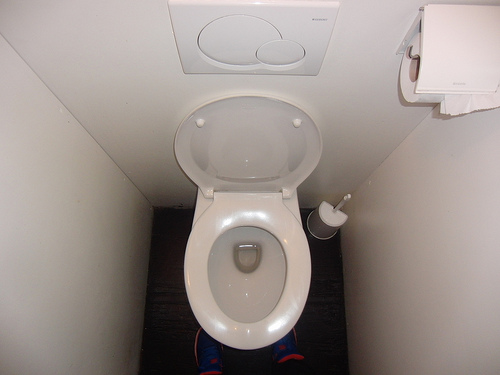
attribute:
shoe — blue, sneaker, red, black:
[194, 326, 226, 374]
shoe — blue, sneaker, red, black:
[269, 326, 305, 373]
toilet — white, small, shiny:
[172, 92, 324, 351]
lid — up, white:
[173, 92, 325, 201]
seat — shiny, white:
[183, 193, 313, 351]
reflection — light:
[219, 210, 274, 229]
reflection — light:
[267, 295, 299, 335]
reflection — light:
[209, 318, 228, 331]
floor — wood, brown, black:
[140, 204, 348, 374]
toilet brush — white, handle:
[332, 193, 353, 213]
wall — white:
[341, 104, 499, 374]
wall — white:
[0, 1, 498, 209]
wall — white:
[0, 33, 154, 374]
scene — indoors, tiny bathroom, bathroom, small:
[1, 1, 499, 375]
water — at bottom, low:
[231, 239, 264, 277]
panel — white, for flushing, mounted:
[167, 1, 343, 77]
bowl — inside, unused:
[208, 225, 288, 323]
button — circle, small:
[256, 39, 306, 66]